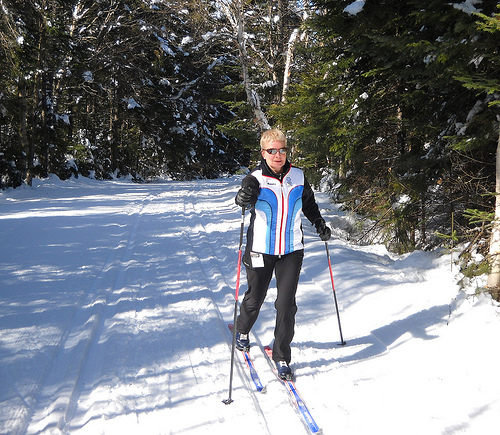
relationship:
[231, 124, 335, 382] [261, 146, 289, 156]
woman has goggles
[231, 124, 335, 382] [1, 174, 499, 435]
woman skiing through snow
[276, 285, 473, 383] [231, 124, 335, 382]
shadow of woman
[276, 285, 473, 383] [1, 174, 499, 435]
shadow on snow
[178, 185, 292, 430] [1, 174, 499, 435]
tracks in snow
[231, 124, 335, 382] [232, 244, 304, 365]
woman wearing pant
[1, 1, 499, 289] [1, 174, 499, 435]
trees lining snow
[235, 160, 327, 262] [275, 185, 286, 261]
coat has zipper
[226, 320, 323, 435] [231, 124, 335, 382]
skiis under woman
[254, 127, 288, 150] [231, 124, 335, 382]
hair of woman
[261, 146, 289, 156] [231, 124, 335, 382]
goggles on woman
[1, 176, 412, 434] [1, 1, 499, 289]
shadow of trees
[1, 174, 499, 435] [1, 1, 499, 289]
snow between trees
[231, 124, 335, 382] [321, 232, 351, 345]
woman holding stick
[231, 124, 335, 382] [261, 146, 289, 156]
woman wearing goggles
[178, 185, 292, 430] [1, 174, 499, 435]
tracks on snow